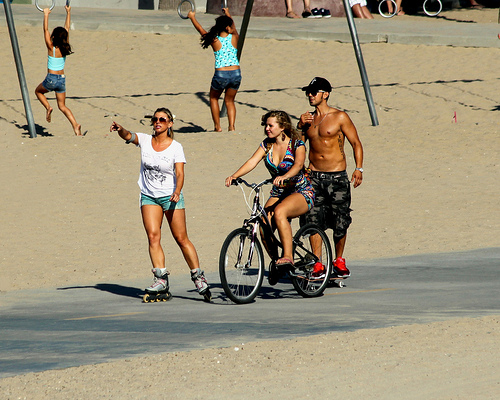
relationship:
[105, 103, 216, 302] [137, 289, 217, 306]
woman on roller-blades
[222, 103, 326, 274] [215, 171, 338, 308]
woman riding a bicycle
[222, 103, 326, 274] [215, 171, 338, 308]
woman on bicycle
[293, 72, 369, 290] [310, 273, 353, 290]
man on skateboard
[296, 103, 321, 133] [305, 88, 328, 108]
right hand near face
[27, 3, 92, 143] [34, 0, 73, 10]
woman on metal rings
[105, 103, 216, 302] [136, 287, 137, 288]
woman in skates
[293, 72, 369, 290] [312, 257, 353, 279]
man wearing sneakers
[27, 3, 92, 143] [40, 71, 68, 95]
girl wearing short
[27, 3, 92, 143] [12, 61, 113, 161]
girl playing in sand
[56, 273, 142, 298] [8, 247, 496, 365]
shadow on road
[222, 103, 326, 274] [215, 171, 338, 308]
woman riding bike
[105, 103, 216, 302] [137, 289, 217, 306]
woman wearing roller skates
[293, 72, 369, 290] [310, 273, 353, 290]
man riding skateboard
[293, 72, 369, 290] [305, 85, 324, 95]
man wearing sunglasses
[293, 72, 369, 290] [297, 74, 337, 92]
man wearing black hat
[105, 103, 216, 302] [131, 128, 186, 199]
woman wearing shirt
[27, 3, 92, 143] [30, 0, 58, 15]
girl hanging from metal rings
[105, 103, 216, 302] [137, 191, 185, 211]
woman wearing shorts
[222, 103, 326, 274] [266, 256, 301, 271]
woman wearing flip flops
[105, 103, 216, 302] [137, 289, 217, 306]
woman on roller skates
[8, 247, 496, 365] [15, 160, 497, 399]
path dividing sand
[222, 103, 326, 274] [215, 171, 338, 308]
woman on a bicycle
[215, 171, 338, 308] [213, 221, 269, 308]
bicycle has front tire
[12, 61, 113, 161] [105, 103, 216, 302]
sand behind woman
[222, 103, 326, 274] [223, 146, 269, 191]
woman has right hand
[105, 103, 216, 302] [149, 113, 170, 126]
woman has sunglasses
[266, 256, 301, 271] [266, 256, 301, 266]
flip flops wearing flip flops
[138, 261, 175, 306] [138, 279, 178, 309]
rollerskate on foot